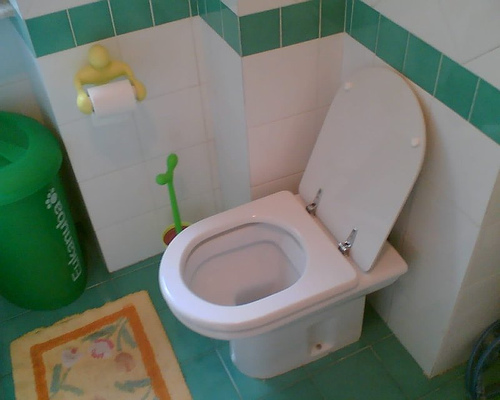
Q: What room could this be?
A: It is a bathroom.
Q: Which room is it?
A: It is a bathroom.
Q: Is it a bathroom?
A: Yes, it is a bathroom.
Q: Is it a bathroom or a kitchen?
A: It is a bathroom.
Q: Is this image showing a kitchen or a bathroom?
A: It is showing a bathroom.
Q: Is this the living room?
A: No, it is the bathroom.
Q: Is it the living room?
A: No, it is the bathroom.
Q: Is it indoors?
A: Yes, it is indoors.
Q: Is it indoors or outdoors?
A: It is indoors.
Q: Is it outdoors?
A: No, it is indoors.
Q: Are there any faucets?
A: No, there are no faucets.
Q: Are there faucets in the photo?
A: No, there are no faucets.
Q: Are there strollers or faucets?
A: No, there are no faucets or strollers.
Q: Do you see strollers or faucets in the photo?
A: No, there are no faucets or strollers.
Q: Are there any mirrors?
A: No, there are no mirrors.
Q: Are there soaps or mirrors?
A: No, there are no mirrors or soaps.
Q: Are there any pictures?
A: No, there are no pictures.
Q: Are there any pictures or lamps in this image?
A: No, there are no pictures or lamps.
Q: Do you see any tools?
A: No, there are no tools.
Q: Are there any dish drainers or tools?
A: No, there are no tools or dish drainers.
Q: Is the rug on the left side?
A: Yes, the rug is on the left of the image.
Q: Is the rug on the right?
A: No, the rug is on the left of the image.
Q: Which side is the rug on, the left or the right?
A: The rug is on the left of the image.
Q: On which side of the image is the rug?
A: The rug is on the left of the image.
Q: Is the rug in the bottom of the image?
A: Yes, the rug is in the bottom of the image.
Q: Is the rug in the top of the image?
A: No, the rug is in the bottom of the image.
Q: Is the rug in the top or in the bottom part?
A: The rug is in the bottom of the image.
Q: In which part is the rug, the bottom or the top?
A: The rug is in the bottom of the image.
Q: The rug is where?
A: The rug is on the floor.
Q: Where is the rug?
A: The rug is on the floor.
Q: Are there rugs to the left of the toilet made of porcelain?
A: Yes, there is a rug to the left of the toilet.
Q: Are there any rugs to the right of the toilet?
A: No, the rug is to the left of the toilet.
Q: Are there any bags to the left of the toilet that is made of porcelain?
A: No, there is a rug to the left of the toilet.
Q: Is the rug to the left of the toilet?
A: Yes, the rug is to the left of the toilet.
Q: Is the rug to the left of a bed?
A: No, the rug is to the left of the toilet.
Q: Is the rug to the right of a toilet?
A: No, the rug is to the left of a toilet.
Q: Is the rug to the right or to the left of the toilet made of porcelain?
A: The rug is to the left of the toilet.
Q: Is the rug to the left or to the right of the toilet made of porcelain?
A: The rug is to the left of the toilet.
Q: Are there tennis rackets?
A: No, there are no tennis rackets.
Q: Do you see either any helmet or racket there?
A: No, there are no rackets or helmets.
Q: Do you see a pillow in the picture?
A: No, there are no pillows.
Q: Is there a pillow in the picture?
A: No, there are no pillows.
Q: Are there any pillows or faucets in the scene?
A: No, there are no pillows or faucets.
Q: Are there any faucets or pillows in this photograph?
A: No, there are no pillows or faucets.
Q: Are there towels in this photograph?
A: No, there are no towels.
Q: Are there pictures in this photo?
A: No, there are no pictures.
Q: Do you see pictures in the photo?
A: No, there are no pictures.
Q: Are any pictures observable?
A: No, there are no pictures.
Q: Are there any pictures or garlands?
A: No, there are no pictures or garlands.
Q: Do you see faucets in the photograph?
A: No, there are no faucets.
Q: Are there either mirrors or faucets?
A: No, there are no faucets or mirrors.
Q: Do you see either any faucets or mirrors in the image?
A: No, there are no faucets or mirrors.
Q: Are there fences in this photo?
A: No, there are no fences.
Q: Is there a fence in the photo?
A: No, there are no fences.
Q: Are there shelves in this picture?
A: No, there are no shelves.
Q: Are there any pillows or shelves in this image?
A: No, there are no shelves or pillows.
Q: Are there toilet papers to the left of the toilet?
A: Yes, there is a toilet paper to the left of the toilet.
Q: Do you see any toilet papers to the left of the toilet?
A: Yes, there is a toilet paper to the left of the toilet.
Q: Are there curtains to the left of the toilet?
A: No, there is a toilet paper to the left of the toilet.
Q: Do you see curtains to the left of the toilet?
A: No, there is a toilet paper to the left of the toilet.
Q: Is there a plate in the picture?
A: No, there are no plates.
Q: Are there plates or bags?
A: No, there are no plates or bags.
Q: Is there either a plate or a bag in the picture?
A: No, there are no plates or bags.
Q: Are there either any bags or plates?
A: No, there are no plates or bags.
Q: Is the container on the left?
A: Yes, the container is on the left of the image.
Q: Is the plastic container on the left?
A: Yes, the container is on the left of the image.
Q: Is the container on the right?
A: No, the container is on the left of the image.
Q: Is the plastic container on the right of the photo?
A: No, the container is on the left of the image.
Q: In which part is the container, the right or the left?
A: The container is on the left of the image.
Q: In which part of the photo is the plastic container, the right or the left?
A: The container is on the left of the image.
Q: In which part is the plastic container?
A: The container is on the left of the image.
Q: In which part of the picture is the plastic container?
A: The container is on the left of the image.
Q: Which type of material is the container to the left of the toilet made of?
A: The container is made of plastic.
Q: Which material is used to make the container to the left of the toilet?
A: The container is made of plastic.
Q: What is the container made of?
A: The container is made of plastic.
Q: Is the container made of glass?
A: No, the container is made of plastic.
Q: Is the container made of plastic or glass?
A: The container is made of plastic.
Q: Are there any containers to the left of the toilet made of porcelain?
A: Yes, there is a container to the left of the toilet.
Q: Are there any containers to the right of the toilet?
A: No, the container is to the left of the toilet.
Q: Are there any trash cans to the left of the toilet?
A: No, there is a container to the left of the toilet.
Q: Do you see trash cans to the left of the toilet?
A: No, there is a container to the left of the toilet.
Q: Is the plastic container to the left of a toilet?
A: Yes, the container is to the left of a toilet.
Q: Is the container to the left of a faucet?
A: No, the container is to the left of a toilet.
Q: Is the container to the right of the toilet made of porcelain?
A: No, the container is to the left of the toilet.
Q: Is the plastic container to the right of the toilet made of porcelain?
A: No, the container is to the left of the toilet.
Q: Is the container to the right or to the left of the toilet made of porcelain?
A: The container is to the left of the toilet.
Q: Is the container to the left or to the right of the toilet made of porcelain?
A: The container is to the left of the toilet.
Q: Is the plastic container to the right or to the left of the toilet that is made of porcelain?
A: The container is to the left of the toilet.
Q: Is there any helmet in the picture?
A: No, there are no helmets.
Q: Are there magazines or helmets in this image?
A: No, there are no helmets or magazines.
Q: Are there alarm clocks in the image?
A: No, there are no alarm clocks.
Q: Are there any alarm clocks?
A: No, there are no alarm clocks.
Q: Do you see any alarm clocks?
A: No, there are no alarm clocks.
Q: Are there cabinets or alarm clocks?
A: No, there are no alarm clocks or cabinets.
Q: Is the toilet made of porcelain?
A: Yes, the toilet is made of porcelain.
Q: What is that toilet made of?
A: The toilet is made of porcelain.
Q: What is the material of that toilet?
A: The toilet is made of porcelain.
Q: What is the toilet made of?
A: The toilet is made of porcelain.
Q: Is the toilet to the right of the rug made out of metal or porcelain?
A: The toilet is made of porcelain.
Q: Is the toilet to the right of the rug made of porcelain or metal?
A: The toilet is made of porcelain.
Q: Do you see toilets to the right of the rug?
A: Yes, there is a toilet to the right of the rug.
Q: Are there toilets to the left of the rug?
A: No, the toilet is to the right of the rug.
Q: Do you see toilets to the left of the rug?
A: No, the toilet is to the right of the rug.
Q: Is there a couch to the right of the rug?
A: No, there is a toilet to the right of the rug.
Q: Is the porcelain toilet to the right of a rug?
A: Yes, the toilet is to the right of a rug.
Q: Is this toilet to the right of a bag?
A: No, the toilet is to the right of a rug.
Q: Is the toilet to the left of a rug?
A: No, the toilet is to the right of a rug.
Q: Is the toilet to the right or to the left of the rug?
A: The toilet is to the right of the rug.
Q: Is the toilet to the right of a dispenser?
A: No, the toilet is to the right of the toilet paper.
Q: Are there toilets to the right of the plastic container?
A: Yes, there is a toilet to the right of the container.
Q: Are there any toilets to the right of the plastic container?
A: Yes, there is a toilet to the right of the container.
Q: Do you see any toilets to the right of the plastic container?
A: Yes, there is a toilet to the right of the container.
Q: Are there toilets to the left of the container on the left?
A: No, the toilet is to the right of the container.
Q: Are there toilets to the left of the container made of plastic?
A: No, the toilet is to the right of the container.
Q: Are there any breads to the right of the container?
A: No, there is a toilet to the right of the container.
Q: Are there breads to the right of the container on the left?
A: No, there is a toilet to the right of the container.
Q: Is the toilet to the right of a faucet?
A: No, the toilet is to the right of a toilet paper.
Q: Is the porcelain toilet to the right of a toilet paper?
A: Yes, the toilet is to the right of a toilet paper.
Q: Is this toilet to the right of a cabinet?
A: No, the toilet is to the right of a toilet paper.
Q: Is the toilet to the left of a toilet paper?
A: No, the toilet is to the right of a toilet paper.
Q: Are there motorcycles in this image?
A: No, there are no motorcycles.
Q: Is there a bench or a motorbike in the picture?
A: No, there are no motorcycles or benches.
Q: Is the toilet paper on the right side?
A: No, the toilet paper is on the left of the image.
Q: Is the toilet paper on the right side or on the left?
A: The toilet paper is on the left of the image.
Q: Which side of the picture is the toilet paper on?
A: The toilet paper is on the left of the image.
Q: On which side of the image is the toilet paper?
A: The toilet paper is on the left of the image.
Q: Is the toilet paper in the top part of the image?
A: Yes, the toilet paper is in the top of the image.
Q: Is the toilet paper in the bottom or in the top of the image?
A: The toilet paper is in the top of the image.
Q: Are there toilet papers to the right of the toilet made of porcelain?
A: No, the toilet paper is to the left of the toilet.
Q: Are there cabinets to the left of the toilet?
A: No, there is a toilet paper to the left of the toilet.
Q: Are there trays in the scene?
A: No, there are no trays.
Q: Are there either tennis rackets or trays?
A: No, there are no trays or tennis rackets.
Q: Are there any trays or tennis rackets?
A: No, there are no trays or tennis rackets.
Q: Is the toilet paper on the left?
A: Yes, the toilet paper is on the left of the image.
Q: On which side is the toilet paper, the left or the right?
A: The toilet paper is on the left of the image.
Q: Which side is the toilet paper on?
A: The toilet paper is on the left of the image.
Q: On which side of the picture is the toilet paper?
A: The toilet paper is on the left of the image.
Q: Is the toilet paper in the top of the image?
A: Yes, the toilet paper is in the top of the image.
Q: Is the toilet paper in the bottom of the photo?
A: No, the toilet paper is in the top of the image.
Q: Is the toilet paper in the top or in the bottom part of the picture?
A: The toilet paper is in the top of the image.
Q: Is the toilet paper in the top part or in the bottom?
A: The toilet paper is in the top of the image.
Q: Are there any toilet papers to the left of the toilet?
A: Yes, there is a toilet paper to the left of the toilet.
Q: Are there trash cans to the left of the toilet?
A: No, there is a toilet paper to the left of the toilet.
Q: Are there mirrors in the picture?
A: No, there are no mirrors.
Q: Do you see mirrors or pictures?
A: No, there are no mirrors or pictures.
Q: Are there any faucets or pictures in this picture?
A: No, there are no faucets or pictures.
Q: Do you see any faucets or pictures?
A: No, there are no faucets or pictures.